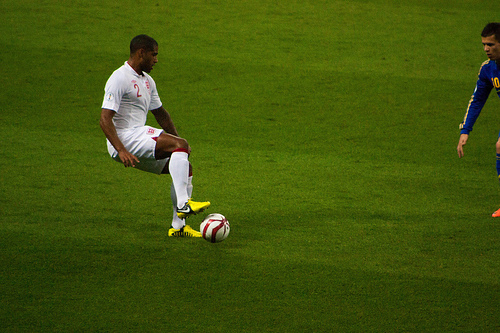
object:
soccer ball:
[199, 212, 232, 243]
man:
[99, 32, 210, 241]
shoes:
[167, 224, 205, 237]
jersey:
[101, 60, 162, 130]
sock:
[169, 148, 192, 204]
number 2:
[132, 83, 144, 97]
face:
[149, 49, 160, 70]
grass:
[3, 245, 500, 333]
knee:
[177, 137, 199, 153]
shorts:
[108, 124, 172, 177]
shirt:
[454, 55, 499, 136]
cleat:
[491, 205, 500, 218]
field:
[1, 3, 500, 331]